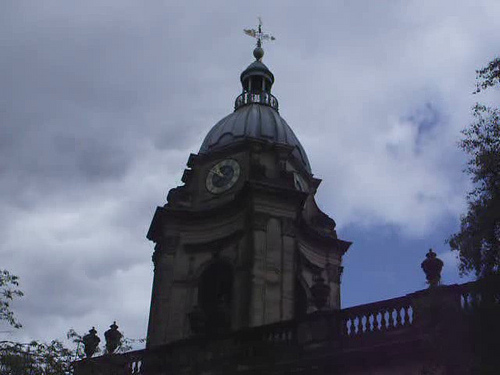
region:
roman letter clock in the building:
[195, 152, 245, 198]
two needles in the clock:
[208, 165, 236, 183]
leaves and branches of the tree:
[471, 83, 499, 266]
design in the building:
[235, 283, 470, 371]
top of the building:
[175, 23, 323, 224]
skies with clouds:
[324, 5, 445, 232]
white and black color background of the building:
[193, 155, 248, 196]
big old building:
[102, 35, 342, 372]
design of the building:
[297, 235, 347, 312]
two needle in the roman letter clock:
[208, 159, 249, 196]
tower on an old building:
[137, 23, 359, 317]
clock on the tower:
[206, 153, 249, 200]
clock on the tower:
[290, 170, 315, 212]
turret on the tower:
[233, 28, 284, 109]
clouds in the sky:
[360, 59, 442, 162]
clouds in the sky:
[30, 48, 133, 220]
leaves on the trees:
[457, 117, 497, 269]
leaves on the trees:
[5, 267, 59, 368]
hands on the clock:
[206, 160, 223, 178]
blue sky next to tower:
[357, 238, 408, 280]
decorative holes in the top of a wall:
[74, 280, 490, 369]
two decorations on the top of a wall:
[80, 321, 127, 359]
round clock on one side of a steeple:
[201, 155, 241, 200]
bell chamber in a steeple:
[189, 245, 241, 340]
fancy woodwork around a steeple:
[146, 185, 358, 254]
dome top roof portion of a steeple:
[193, 101, 322, 179]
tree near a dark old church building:
[445, 52, 497, 303]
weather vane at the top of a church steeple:
[240, 13, 278, 62]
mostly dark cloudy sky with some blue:
[3, 0, 495, 327]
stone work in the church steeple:
[244, 203, 300, 335]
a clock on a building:
[182, 147, 264, 202]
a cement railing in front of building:
[81, 270, 470, 374]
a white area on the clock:
[196, 154, 243, 196]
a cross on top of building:
[231, 12, 308, 82]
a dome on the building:
[157, 104, 322, 156]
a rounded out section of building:
[114, 170, 302, 365]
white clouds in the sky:
[13, 11, 483, 276]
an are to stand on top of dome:
[217, 72, 294, 107]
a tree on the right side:
[422, 48, 497, 328]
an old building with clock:
[117, 32, 370, 361]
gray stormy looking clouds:
[11, 7, 127, 252]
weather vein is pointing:
[228, 19, 289, 111]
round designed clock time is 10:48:
[198, 156, 253, 199]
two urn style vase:
[76, 314, 123, 367]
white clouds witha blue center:
[380, 74, 453, 189]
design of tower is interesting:
[126, 14, 354, 329]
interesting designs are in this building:
[133, 17, 351, 349]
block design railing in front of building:
[110, 305, 439, 364]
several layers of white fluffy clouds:
[20, 155, 137, 320]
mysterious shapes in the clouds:
[38, 98, 174, 208]